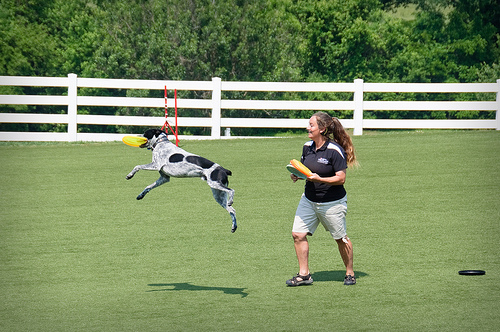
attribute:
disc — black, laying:
[454, 267, 489, 278]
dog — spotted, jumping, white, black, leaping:
[122, 127, 246, 236]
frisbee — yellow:
[120, 132, 149, 148]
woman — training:
[276, 107, 372, 290]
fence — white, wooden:
[0, 67, 500, 138]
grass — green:
[1, 140, 499, 330]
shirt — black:
[296, 141, 350, 204]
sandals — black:
[282, 270, 360, 289]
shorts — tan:
[287, 195, 352, 243]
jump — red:
[157, 82, 184, 151]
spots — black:
[169, 149, 234, 185]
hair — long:
[314, 110, 355, 163]